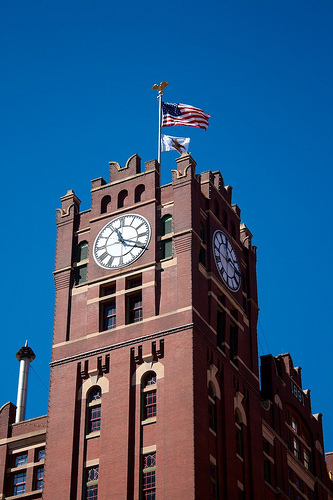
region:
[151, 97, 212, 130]
red white and blue flag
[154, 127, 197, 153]
flag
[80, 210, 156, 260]
black and white clock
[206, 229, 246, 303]
clock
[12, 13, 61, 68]
blue sky with no clouds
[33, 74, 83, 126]
blue sky with no clouds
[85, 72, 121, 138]
blue sky with no clouds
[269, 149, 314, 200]
blue sky with no clouds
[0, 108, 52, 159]
blue sky with no clouds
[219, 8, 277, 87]
blue sky with no clouds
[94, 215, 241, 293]
the tower has two clocks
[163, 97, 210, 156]
the tower has two flags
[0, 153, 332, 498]
the building is brown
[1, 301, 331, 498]
the window frames are red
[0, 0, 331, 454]
the sky is clear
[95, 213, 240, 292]
the clocks tell the time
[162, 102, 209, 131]
the flag is the us flag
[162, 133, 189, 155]
a white flag with a symbol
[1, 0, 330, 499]
the scene takes place outdoors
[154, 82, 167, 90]
a gold eagle on the pole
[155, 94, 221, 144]
Red white and blue flag on pole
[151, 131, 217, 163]
Flag on a pole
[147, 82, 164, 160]
Tall silver flag pole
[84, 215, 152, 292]
Black and white clock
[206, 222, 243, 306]
Black and white clock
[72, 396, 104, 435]
Red and white window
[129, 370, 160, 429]
Red and white window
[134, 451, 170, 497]
Red and white window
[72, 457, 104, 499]
Red and white window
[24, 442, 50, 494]
Red and white window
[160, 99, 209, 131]
American flag flying in the wind.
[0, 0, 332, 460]
A clear blue sky with no clouds in sight.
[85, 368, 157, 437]
Two windows with rounded tops.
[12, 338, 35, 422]
Silver and black chimney on roof.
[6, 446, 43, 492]
Four windows with panes in them.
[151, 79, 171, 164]
Flagpole with eagle on top.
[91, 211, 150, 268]
Clock says eleven-twenty and is white faced.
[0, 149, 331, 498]
A building is made of bricks.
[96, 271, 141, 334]
Two windows are rectangular in shape.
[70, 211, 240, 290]
Two clock faces are on the building.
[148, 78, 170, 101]
an eagle with open wings is the carved emblem at the top of the flagpole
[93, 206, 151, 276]
one clock faces the sun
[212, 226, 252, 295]
one clock face is in shadow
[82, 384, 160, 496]
the wood trim of the window panes is painted red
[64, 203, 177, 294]
an arched window on each side of the clock face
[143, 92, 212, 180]
the American flag is hoisted above the state flag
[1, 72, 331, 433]
cloudless blue sky behind the clock tower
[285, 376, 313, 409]
the year 1891 has been noted in the building design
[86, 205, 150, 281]
the time in the photograph is 11:20 am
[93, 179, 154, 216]
three arches with no windows above the clock